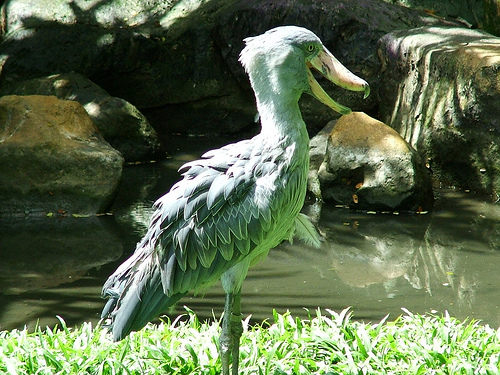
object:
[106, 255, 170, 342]
tail feather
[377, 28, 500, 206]
rock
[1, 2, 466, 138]
rock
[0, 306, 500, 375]
grass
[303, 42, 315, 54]
birds eye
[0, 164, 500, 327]
water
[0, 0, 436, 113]
shadow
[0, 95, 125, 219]
rock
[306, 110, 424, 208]
boulder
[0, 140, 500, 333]
pond shadow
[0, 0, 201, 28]
sunlight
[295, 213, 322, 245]
feather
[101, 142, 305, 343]
feathers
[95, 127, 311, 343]
body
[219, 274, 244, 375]
leg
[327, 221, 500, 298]
reflection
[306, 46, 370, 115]
beak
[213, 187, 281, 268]
abdomen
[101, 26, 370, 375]
animal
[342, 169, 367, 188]
holes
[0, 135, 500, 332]
pond